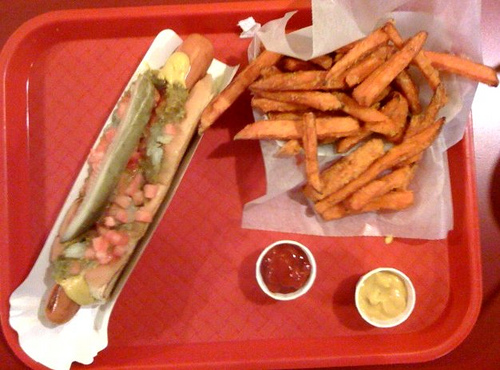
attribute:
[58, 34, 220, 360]
hotdog — foot long, brown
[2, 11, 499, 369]
tray — red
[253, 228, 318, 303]
cup — small, white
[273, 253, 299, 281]
ketchup — red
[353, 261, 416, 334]
cup — small, white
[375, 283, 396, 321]
mustard — yellow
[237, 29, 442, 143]
sweet potato fries — cooked, orange, brown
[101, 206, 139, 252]
tomatoes — chopped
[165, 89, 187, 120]
relish — green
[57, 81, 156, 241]
pickle — green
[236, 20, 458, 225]
paper tray — white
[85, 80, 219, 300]
hotdog bun — long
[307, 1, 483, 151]
parchment paper — white